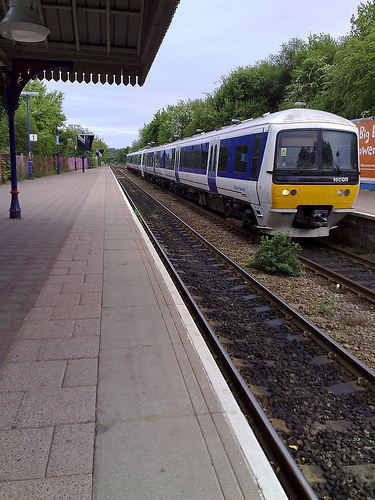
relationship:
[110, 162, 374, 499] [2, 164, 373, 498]
track on ground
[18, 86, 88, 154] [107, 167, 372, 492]
trees next to tracks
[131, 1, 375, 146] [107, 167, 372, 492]
trees next to tracks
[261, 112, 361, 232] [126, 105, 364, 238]
cockpit of train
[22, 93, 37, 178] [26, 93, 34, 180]
light pole made of light pole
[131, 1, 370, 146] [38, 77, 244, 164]
trees in background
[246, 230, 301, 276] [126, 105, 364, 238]
bush in front of train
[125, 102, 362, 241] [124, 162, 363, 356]
long train sits on tracks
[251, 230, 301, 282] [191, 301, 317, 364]
bush on tracks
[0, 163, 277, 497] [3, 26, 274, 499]
platform at station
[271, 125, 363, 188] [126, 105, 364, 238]
windshield of train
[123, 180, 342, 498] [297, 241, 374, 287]
dark gravel on tracks